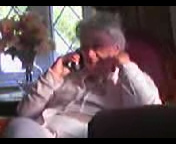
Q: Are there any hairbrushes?
A: No, there are no hairbrushes.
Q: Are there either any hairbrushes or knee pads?
A: No, there are no hairbrushes or knee pads.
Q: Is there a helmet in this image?
A: No, there are no helmets.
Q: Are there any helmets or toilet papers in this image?
A: No, there are no helmets or toilet papers.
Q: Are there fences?
A: No, there are no fences.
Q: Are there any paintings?
A: No, there are no paintings.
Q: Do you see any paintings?
A: No, there are no paintings.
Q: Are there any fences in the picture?
A: No, there are no fences.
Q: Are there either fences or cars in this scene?
A: No, there are no fences or cars.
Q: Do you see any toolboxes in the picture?
A: No, there are no toolboxes.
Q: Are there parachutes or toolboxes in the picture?
A: No, there are no toolboxes or parachutes.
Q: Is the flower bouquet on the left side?
A: Yes, the flower bouquet is on the left of the image.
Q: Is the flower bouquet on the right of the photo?
A: No, the flower bouquet is on the left of the image.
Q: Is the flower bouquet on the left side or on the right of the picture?
A: The flower bouquet is on the left of the image.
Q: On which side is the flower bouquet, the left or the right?
A: The flower bouquet is on the left of the image.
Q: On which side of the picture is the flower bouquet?
A: The flower bouquet is on the left of the image.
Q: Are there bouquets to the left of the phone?
A: Yes, there is a bouquet to the left of the phone.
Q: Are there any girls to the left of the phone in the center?
A: No, there is a bouquet to the left of the phone.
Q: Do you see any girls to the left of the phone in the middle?
A: No, there is a bouquet to the left of the phone.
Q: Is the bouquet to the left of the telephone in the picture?
A: Yes, the bouquet is to the left of the telephone.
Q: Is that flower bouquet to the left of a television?
A: No, the flower bouquet is to the left of the telephone.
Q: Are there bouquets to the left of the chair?
A: Yes, there is a bouquet to the left of the chair.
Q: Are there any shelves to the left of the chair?
A: No, there is a bouquet to the left of the chair.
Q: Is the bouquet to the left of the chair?
A: Yes, the bouquet is to the left of the chair.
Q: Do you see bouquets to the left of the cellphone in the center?
A: Yes, there is a bouquet to the left of the cellphone.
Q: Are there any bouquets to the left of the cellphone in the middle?
A: Yes, there is a bouquet to the left of the cellphone.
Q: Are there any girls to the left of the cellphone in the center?
A: No, there is a bouquet to the left of the cellphone.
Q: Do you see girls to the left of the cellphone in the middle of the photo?
A: No, there is a bouquet to the left of the cellphone.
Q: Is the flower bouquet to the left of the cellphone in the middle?
A: Yes, the flower bouquet is to the left of the mobile phone.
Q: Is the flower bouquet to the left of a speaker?
A: No, the flower bouquet is to the left of the mobile phone.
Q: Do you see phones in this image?
A: Yes, there is a phone.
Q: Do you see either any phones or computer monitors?
A: Yes, there is a phone.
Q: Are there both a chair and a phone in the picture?
A: Yes, there are both a phone and a chair.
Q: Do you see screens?
A: No, there are no screens.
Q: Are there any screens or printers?
A: No, there are no screens or printers.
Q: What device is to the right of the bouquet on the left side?
A: The device is a phone.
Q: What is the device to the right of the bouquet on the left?
A: The device is a phone.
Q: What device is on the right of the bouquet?
A: The device is a phone.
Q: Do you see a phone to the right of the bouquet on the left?
A: Yes, there is a phone to the right of the flower bouquet.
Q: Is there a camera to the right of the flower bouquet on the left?
A: No, there is a phone to the right of the flower bouquet.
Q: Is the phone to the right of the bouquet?
A: Yes, the phone is to the right of the bouquet.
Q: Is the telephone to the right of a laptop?
A: No, the telephone is to the right of the bouquet.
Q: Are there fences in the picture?
A: No, there are no fences.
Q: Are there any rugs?
A: No, there are no rugs.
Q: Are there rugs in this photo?
A: No, there are no rugs.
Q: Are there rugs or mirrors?
A: No, there are no rugs or mirrors.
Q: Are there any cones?
A: No, there are no cones.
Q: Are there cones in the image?
A: No, there are no cones.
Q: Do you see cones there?
A: No, there are no cones.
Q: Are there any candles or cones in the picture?
A: No, there are no cones or candles.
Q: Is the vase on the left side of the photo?
A: Yes, the vase is on the left of the image.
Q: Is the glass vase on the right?
A: No, the vase is on the left of the image.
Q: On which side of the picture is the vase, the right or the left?
A: The vase is on the left of the image.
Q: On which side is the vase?
A: The vase is on the left of the image.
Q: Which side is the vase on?
A: The vase is on the left of the image.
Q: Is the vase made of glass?
A: Yes, the vase is made of glass.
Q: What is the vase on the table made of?
A: The vase is made of glass.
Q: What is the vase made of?
A: The vase is made of glass.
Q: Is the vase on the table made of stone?
A: No, the vase is made of glass.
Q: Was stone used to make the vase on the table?
A: No, the vase is made of glass.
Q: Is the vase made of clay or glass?
A: The vase is made of glass.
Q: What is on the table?
A: The vase is on the table.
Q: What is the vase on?
A: The vase is on the table.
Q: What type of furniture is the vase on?
A: The vase is on the table.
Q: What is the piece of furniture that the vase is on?
A: The piece of furniture is a table.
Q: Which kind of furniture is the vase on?
A: The vase is on the table.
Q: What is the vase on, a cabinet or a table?
A: The vase is on a table.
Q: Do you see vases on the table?
A: Yes, there is a vase on the table.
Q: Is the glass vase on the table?
A: Yes, the vase is on the table.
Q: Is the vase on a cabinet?
A: No, the vase is on the table.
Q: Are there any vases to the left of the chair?
A: Yes, there is a vase to the left of the chair.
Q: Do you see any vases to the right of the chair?
A: No, the vase is to the left of the chair.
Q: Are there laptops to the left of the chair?
A: No, there is a vase to the left of the chair.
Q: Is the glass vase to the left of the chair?
A: Yes, the vase is to the left of the chair.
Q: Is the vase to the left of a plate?
A: No, the vase is to the left of the chair.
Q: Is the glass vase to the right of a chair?
A: No, the vase is to the left of a chair.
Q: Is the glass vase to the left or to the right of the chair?
A: The vase is to the left of the chair.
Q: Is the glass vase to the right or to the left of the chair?
A: The vase is to the left of the chair.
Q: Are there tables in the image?
A: Yes, there is a table.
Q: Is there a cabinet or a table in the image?
A: Yes, there is a table.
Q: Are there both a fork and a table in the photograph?
A: No, there is a table but no forks.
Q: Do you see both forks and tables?
A: No, there is a table but no forks.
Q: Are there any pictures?
A: No, there are no pictures.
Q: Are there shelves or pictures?
A: No, there are no pictures or shelves.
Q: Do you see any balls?
A: No, there are no balls.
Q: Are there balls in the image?
A: No, there are no balls.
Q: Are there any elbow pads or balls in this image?
A: No, there are no balls or elbow pads.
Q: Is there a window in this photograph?
A: Yes, there are windows.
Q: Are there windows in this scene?
A: Yes, there are windows.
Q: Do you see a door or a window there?
A: Yes, there are windows.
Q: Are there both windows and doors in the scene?
A: No, there are windows but no doors.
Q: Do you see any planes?
A: No, there are no planes.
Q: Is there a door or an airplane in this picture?
A: No, there are no airplanes or doors.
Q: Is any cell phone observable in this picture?
A: Yes, there is a cell phone.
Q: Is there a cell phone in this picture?
A: Yes, there is a cell phone.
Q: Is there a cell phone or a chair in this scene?
A: Yes, there is a cell phone.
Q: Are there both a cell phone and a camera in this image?
A: No, there is a cell phone but no cameras.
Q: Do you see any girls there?
A: No, there are no girls.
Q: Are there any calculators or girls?
A: No, there are no girls or calculators.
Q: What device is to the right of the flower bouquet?
A: The device is a cell phone.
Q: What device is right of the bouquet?
A: The device is a cell phone.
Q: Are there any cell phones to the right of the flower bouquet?
A: Yes, there is a cell phone to the right of the flower bouquet.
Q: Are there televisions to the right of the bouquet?
A: No, there is a cell phone to the right of the bouquet.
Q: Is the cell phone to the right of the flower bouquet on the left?
A: Yes, the cell phone is to the right of the flower bouquet.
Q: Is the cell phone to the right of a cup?
A: No, the cell phone is to the right of the flower bouquet.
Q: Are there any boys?
A: No, there are no boys.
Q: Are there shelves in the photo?
A: No, there are no shelves.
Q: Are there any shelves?
A: No, there are no shelves.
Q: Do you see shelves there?
A: No, there are no shelves.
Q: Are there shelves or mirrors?
A: No, there are no shelves or mirrors.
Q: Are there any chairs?
A: Yes, there is a chair.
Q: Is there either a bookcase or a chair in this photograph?
A: Yes, there is a chair.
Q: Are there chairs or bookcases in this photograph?
A: Yes, there is a chair.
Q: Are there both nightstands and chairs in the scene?
A: No, there is a chair but no nightstands.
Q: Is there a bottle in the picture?
A: No, there are no bottles.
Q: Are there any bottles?
A: No, there are no bottles.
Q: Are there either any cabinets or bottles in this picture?
A: No, there are no bottles or cabinets.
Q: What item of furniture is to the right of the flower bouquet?
A: The piece of furniture is a chair.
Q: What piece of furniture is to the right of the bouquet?
A: The piece of furniture is a chair.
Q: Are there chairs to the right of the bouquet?
A: Yes, there is a chair to the right of the bouquet.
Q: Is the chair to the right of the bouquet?
A: Yes, the chair is to the right of the bouquet.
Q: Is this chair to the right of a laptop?
A: No, the chair is to the right of the bouquet.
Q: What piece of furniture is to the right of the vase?
A: The piece of furniture is a chair.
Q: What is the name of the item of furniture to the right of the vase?
A: The piece of furniture is a chair.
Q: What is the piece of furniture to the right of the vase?
A: The piece of furniture is a chair.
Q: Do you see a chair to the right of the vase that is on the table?
A: Yes, there is a chair to the right of the vase.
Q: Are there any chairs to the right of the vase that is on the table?
A: Yes, there is a chair to the right of the vase.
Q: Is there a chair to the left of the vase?
A: No, the chair is to the right of the vase.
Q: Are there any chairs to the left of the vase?
A: No, the chair is to the right of the vase.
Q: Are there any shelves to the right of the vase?
A: No, there is a chair to the right of the vase.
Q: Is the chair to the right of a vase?
A: Yes, the chair is to the right of a vase.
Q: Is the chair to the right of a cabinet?
A: No, the chair is to the right of a vase.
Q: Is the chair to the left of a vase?
A: No, the chair is to the right of a vase.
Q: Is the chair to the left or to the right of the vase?
A: The chair is to the right of the vase.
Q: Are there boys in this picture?
A: No, there are no boys.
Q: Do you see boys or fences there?
A: No, there are no boys or fences.